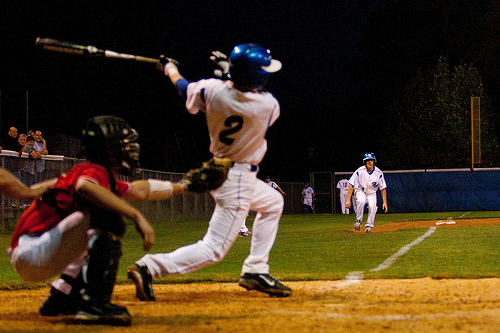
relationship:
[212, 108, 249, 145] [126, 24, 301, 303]
blue on baseball player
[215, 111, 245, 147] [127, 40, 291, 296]
number on back player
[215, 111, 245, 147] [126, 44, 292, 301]
number on back baseball player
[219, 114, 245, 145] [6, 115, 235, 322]
number on back child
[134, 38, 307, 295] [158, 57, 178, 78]
baseball player wearing glove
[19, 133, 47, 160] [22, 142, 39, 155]
person wearing green shirt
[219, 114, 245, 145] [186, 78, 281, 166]
number on back jersey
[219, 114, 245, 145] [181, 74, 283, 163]
number on shirt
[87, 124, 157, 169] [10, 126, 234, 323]
mask of child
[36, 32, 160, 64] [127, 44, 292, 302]
bat of baseball player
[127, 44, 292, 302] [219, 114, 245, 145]
baseball player with number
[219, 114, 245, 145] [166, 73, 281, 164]
number on shirt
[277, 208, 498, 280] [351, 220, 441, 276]
grass has stripes